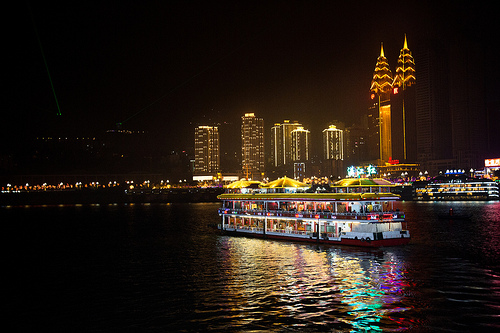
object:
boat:
[219, 186, 412, 250]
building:
[358, 35, 414, 200]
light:
[361, 30, 426, 93]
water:
[2, 250, 477, 331]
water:
[6, 266, 471, 329]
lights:
[209, 170, 393, 195]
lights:
[58, 161, 257, 210]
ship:
[217, 174, 407, 245]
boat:
[188, 155, 471, 284]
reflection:
[227, 242, 337, 290]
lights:
[287, 174, 332, 241]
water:
[2, 233, 497, 330]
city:
[3, 31, 499, 203]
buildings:
[201, 7, 433, 178]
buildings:
[183, 34, 435, 182]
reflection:
[229, 242, 387, 326]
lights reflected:
[215, 135, 392, 303]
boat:
[195, 166, 450, 256]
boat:
[214, 183, 411, 252]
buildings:
[200, 53, 435, 191]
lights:
[1, 45, 496, 194]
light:
[0, 181, 13, 191]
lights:
[0, 173, 176, 196]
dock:
[0, 185, 235, 208]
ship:
[215, 191, 410, 244]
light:
[293, 214, 297, 218]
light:
[265, 210, 270, 216]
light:
[223, 207, 226, 214]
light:
[367, 213, 385, 218]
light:
[342, 202, 348, 210]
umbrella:
[222, 176, 261, 194]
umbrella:
[264, 176, 305, 191]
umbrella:
[333, 173, 397, 192]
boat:
[209, 184, 402, 246]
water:
[52, 215, 198, 325]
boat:
[422, 178, 499, 200]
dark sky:
[136, 21, 284, 78]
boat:
[210, 169, 412, 251]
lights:
[210, 167, 402, 231]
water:
[173, 246, 411, 314]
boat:
[213, 175, 410, 246]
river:
[0, 205, 499, 331]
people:
[209, 183, 406, 240]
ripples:
[169, 231, 494, 325]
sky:
[46, 11, 271, 89]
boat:
[214, 163, 415, 242]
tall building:
[371, 29, 425, 174]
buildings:
[170, 49, 420, 252]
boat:
[242, 181, 430, 241]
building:
[361, 28, 428, 187]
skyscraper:
[323, 31, 427, 133]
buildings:
[144, 35, 436, 189]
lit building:
[189, 121, 222, 179]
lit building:
[239, 110, 264, 179]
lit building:
[269, 116, 280, 174]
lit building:
[287, 123, 309, 163]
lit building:
[322, 124, 347, 162]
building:
[321, 120, 345, 180]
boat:
[205, 159, 398, 242]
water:
[116, 244, 296, 318]